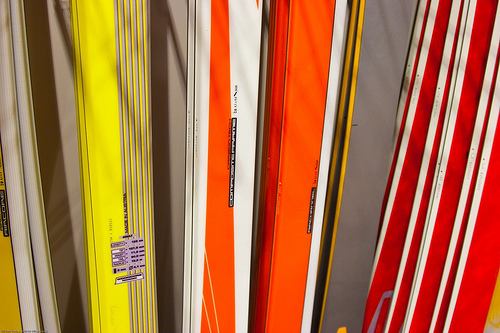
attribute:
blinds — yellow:
[71, 1, 161, 331]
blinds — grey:
[318, 0, 415, 330]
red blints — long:
[355, 0, 497, 332]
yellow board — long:
[70, 1, 180, 331]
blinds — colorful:
[0, 1, 160, 331]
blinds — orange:
[181, 1, 350, 331]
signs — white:
[103, 237, 151, 288]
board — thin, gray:
[364, 22, 395, 210]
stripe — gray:
[316, 5, 388, 331]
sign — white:
[0, 0, 160, 332]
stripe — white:
[185, 116, 204, 301]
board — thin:
[327, 42, 442, 187]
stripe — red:
[200, 0, 242, 332]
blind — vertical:
[49, 116, 271, 327]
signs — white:
[97, 220, 161, 290]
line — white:
[439, 61, 496, 328]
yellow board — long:
[67, 2, 157, 331]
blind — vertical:
[262, 2, 352, 332]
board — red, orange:
[183, 64, 266, 215]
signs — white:
[111, 234, 148, 285]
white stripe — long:
[234, 131, 256, 250]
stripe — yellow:
[70, 1, 160, 331]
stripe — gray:
[149, 0, 198, 331]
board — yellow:
[72, 7, 164, 330]